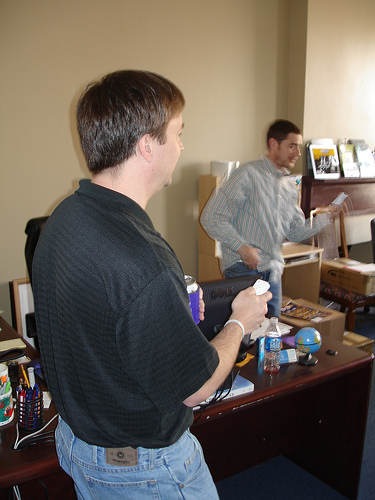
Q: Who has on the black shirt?
A: Closest man.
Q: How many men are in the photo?
A: Two.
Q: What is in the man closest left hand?
A: Can.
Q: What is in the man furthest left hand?
A: Controller.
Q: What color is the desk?
A: Brown.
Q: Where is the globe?
A: On desk.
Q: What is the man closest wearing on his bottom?
A: Jeans.